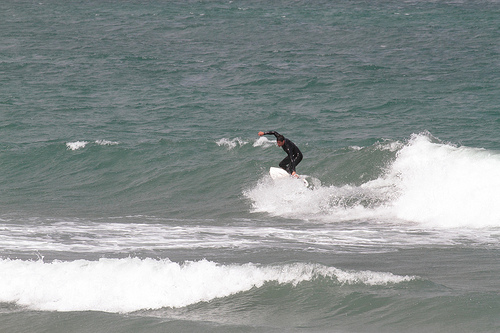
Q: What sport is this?
A: Surfing.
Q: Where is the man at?
A: Water.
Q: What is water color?
A: Blue.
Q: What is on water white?
A: Waves.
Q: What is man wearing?
A: Swimsuit.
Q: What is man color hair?
A: Black.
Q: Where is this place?
A: Ocean.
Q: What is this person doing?
A: Surfing.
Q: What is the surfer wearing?
A: Wet suit.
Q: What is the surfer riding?
A: Wave.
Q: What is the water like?
A: Rough.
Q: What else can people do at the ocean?
A: Swim.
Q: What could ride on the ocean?
A: Boat.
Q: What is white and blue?
A: Waves.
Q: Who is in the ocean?
A: A person.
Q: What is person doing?
A: Surfing.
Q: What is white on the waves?
A: The caps.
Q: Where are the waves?
A: In water.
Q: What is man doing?
A: Surfing.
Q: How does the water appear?
A: Choppy.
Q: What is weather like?
A: Clear and cloudy.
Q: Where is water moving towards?
A: The shore.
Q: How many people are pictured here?
A: One.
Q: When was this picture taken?
A: Daytime.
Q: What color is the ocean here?
A: Blue.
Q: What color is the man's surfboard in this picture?
A: White.